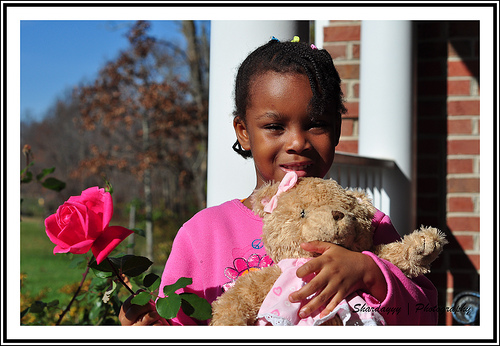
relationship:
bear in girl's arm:
[208, 170, 450, 326] [379, 262, 442, 331]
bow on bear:
[260, 173, 292, 223] [208, 170, 450, 326]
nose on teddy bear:
[333, 209, 344, 222] [206, 180, 449, 324]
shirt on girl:
[142, 188, 440, 324] [118, 40, 438, 326]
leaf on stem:
[156, 296, 181, 322] [150, 290, 164, 302]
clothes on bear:
[253, 254, 391, 326] [213, 170, 445, 326]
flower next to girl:
[44, 185, 134, 265] [118, 40, 438, 326]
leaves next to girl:
[120, 254, 172, 346] [89, 259, 160, 283]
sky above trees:
[21, 22, 213, 129] [27, 27, 211, 222]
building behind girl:
[202, 22, 412, 242] [118, 40, 438, 326]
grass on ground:
[28, 265, 78, 303] [16, 282, 70, 316]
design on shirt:
[220, 254, 275, 277] [154, 197, 439, 325]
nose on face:
[284, 129, 314, 154] [245, 69, 336, 183]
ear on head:
[231, 107, 246, 163] [234, 33, 350, 185]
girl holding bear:
[118, 40, 438, 326] [213, 170, 445, 326]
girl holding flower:
[118, 40, 438, 326] [44, 185, 134, 265]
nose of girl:
[284, 129, 314, 157] [118, 40, 438, 326]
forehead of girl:
[240, 69, 334, 114] [118, 40, 438, 326]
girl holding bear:
[172, 33, 349, 230] [245, 167, 409, 325]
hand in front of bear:
[289, 238, 369, 318] [213, 170, 445, 326]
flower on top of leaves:
[44, 185, 134, 265] [155, 275, 213, 322]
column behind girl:
[358, 20, 417, 237] [150, 32, 440, 321]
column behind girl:
[200, 17, 310, 209] [150, 32, 440, 321]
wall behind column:
[319, 22, 481, 324] [358, 20, 417, 237]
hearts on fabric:
[264, 281, 286, 313] [254, 256, 389, 324]